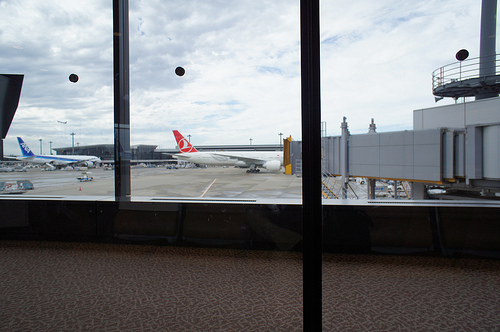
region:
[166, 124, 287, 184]
A plane on a runway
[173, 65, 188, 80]
A black circle on the window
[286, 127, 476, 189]
A rectangle portion of the airport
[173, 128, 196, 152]
A red part of the tail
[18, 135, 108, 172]
A blue and white plane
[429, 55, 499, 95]
A metal fence on a pole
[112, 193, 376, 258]
Reflection in the glass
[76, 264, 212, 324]
The carpet has a brown pattern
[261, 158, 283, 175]
A plane's jet engine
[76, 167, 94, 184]
A small car drives on cement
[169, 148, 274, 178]
the plane is white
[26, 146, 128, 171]
the plane is white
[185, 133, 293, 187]
the plane is white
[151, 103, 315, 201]
the plane at the airport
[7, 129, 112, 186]
the plane at the airport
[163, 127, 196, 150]
red and white tail on plane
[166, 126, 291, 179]
airplane on tarmac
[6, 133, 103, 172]
blue and white airplane on tarmac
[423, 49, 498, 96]
black fenced balcony on building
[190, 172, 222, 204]
line drawn on tarmac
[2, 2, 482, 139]
sky full of clouds with small patches of blue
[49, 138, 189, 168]
airport building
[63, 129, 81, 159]
talll street lamps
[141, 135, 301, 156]
long grey bridge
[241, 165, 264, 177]
wheels underneath airplane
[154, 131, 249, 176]
Airplane on the tarmac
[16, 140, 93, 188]
Airplane on the tarmac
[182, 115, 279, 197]
Airplane on the tarmac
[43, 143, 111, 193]
Airplane on the tarmac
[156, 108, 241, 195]
Airplane on the tarmac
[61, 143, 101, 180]
Airplane on the tarmac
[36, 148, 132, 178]
Airplane on the tarmac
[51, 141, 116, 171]
Airplane on the tarmac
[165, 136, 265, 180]
red and white airplane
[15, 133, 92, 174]
white and blue airplane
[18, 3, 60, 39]
white clouds in blue sky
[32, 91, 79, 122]
white clouds in blue sky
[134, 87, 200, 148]
white clouds in blue sky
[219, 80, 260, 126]
white clouds in blue sky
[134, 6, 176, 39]
white clouds in blue sky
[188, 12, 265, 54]
white clouds in blue sky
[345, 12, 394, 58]
white clouds in blue sky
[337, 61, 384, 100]
white clouds in blue sky